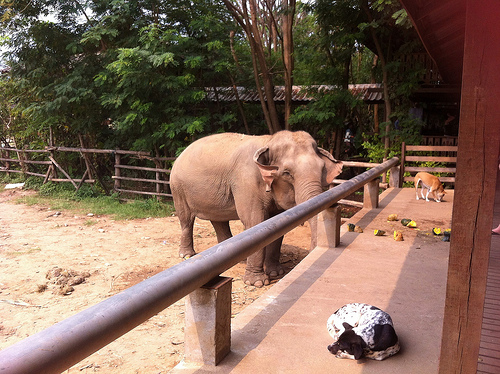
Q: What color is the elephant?
A: Light Brown.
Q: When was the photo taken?
A: Daytime.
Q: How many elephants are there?
A: One.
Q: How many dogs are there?
A: Two.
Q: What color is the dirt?
A: Tan.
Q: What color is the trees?
A: Green.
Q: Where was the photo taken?
A: Zoo.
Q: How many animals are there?
A: Three.